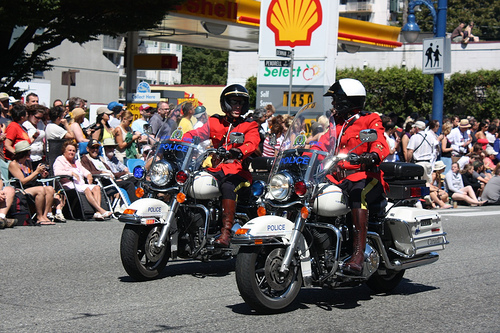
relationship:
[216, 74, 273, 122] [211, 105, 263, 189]
head of person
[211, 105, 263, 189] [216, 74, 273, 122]
person with head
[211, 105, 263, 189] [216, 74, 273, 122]
person has head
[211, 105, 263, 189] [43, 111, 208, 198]
person in crowd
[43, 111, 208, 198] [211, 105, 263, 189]
crowd of person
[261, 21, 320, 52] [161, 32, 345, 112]
sign on station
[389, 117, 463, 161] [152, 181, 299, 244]
people on motorcycles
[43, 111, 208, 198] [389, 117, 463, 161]
crowd of people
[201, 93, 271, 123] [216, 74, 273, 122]
helmet on head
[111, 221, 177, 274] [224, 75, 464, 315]
wheel on motorcycle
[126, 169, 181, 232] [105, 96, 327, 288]
fender on motorcycle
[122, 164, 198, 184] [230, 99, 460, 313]
headlights on motorcycle